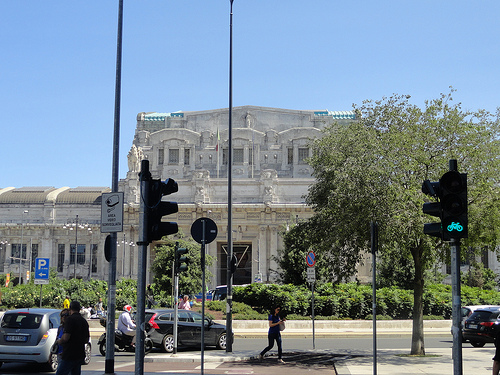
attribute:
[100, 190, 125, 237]
sign — black, white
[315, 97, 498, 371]
tree — large, green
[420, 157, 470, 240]
light — green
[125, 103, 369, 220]
white building — large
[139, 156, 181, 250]
street light — black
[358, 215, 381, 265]
sign — white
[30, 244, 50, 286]
sign — blue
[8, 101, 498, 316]
building — museum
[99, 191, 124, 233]
sign — rectangular, white, black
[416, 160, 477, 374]
lamp — street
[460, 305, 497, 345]
vehicle — black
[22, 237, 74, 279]
sign — blue, white, rectangular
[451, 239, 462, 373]
pole — metal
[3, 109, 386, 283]
building — white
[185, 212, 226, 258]
sign — round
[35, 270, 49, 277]
arrow — white